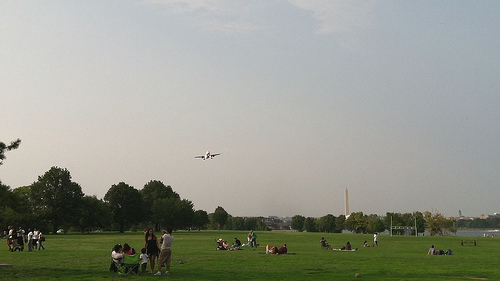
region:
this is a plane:
[192, 143, 226, 163]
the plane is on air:
[189, 138, 221, 163]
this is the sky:
[263, 25, 443, 175]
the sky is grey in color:
[285, 7, 440, 142]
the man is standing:
[157, 224, 182, 264]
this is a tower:
[342, 183, 356, 207]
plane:
[184, 138, 229, 173]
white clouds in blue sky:
[327, 65, 382, 103]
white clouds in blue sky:
[341, 152, 363, 180]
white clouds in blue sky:
[428, 135, 469, 192]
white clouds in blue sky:
[67, 36, 111, 63]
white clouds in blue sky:
[54, 51, 99, 99]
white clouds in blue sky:
[90, 91, 168, 139]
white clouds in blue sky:
[197, 63, 245, 91]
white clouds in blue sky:
[294, 23, 344, 55]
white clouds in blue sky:
[407, 99, 474, 151]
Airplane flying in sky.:
[193, 138, 231, 177]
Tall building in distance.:
[338, 178, 358, 228]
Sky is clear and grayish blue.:
[379, 118, 440, 176]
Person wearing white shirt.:
[162, 235, 179, 253]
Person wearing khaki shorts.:
[156, 245, 173, 260]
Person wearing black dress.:
[145, 238, 159, 253]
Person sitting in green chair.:
[123, 249, 143, 271]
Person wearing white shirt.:
[373, 230, 379, 241]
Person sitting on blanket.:
[338, 236, 361, 262]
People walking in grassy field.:
[4, 217, 65, 278]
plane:
[184, 141, 226, 168]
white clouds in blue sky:
[313, 18, 358, 45]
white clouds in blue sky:
[382, 113, 409, 148]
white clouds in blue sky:
[314, 65, 361, 90]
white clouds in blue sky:
[302, 180, 321, 199]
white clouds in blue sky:
[407, 111, 438, 151]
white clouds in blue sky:
[62, 22, 89, 54]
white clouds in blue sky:
[162, 37, 193, 67]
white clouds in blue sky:
[37, 80, 80, 114]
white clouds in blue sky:
[120, 36, 160, 81]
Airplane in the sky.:
[195, 149, 220, 162]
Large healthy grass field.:
[3, 230, 498, 280]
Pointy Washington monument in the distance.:
[341, 184, 351, 216]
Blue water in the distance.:
[343, 221, 498, 238]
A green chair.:
[121, 251, 141, 275]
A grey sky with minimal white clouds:
[1, 1, 499, 214]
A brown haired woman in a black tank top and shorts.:
[142, 227, 160, 273]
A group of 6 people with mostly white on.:
[3, 224, 46, 252]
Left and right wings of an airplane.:
[195, 154, 219, 159]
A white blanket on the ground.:
[332, 247, 358, 254]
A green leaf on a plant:
[122, 196, 124, 199]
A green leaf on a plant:
[62, 195, 64, 197]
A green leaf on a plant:
[37, 186, 39, 188]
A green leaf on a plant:
[37, 209, 39, 210]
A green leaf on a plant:
[82, 209, 86, 211]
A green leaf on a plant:
[97, 210, 100, 211]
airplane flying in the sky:
[183, 142, 221, 167]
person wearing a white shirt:
[163, 232, 174, 247]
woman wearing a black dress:
[141, 233, 156, 254]